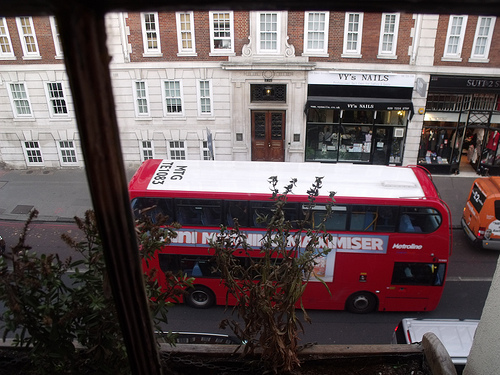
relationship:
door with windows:
[250, 106, 287, 161] [255, 111, 263, 138]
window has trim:
[205, 11, 234, 57] [228, 11, 237, 53]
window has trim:
[255, 14, 284, 57] [255, 13, 258, 48]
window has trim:
[302, 15, 333, 57] [302, 11, 311, 54]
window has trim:
[384, 17, 397, 59] [378, 15, 387, 57]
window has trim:
[446, 18, 461, 53] [458, 19, 463, 61]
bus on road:
[139, 159, 430, 316] [0, 169, 500, 372]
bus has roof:
[139, 159, 430, 316] [155, 156, 415, 210]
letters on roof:
[171, 166, 181, 178] [155, 156, 415, 210]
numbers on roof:
[152, 166, 168, 188] [155, 156, 415, 210]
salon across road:
[308, 69, 412, 182] [0, 169, 500, 372]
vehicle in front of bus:
[459, 176, 498, 247] [139, 159, 430, 316]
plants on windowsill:
[14, 215, 89, 374] [2, 338, 493, 370]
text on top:
[155, 156, 188, 185] [155, 156, 415, 210]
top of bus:
[155, 156, 415, 210] [139, 159, 430, 316]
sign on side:
[142, 230, 400, 259] [126, 206, 445, 297]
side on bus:
[126, 206, 445, 297] [139, 159, 430, 316]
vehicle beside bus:
[400, 314, 499, 357] [139, 159, 430, 316]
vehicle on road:
[400, 314, 499, 357] [0, 169, 500, 372]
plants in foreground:
[14, 215, 89, 374] [14, 240, 498, 371]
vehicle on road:
[459, 176, 498, 247] [2, 231, 494, 297]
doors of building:
[250, 106, 287, 161] [0, 9, 488, 166]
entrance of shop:
[466, 130, 482, 177] [425, 74, 497, 178]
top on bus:
[155, 156, 415, 210] [139, 159, 430, 316]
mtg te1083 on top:
[152, 151, 185, 195] [155, 156, 415, 210]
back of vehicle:
[461, 182, 481, 233] [459, 176, 498, 247]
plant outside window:
[210, 220, 311, 372] [1, 45, 496, 370]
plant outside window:
[2, 231, 127, 367] [1, 45, 496, 370]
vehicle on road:
[400, 314, 499, 357] [2, 231, 494, 297]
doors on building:
[250, 106, 287, 161] [0, 9, 488, 166]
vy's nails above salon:
[324, 71, 389, 84] [303, 67, 431, 169]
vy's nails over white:
[324, 71, 389, 84] [304, 68, 414, 90]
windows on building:
[2, 1, 495, 49] [0, 9, 488, 166]